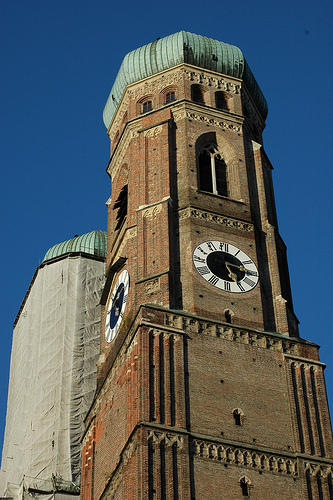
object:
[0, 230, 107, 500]
building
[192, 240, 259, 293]
clock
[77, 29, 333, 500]
tower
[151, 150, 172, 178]
brick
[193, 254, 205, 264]
roman numerals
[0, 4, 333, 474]
sky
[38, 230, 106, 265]
top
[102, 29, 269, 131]
roof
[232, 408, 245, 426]
window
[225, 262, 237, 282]
hands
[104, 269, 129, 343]
clock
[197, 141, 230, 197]
double window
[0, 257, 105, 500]
cover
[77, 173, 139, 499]
left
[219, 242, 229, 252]
12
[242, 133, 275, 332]
shadow